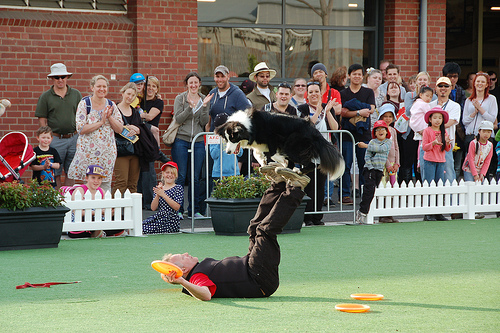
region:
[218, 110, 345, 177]
A dog on the man's feet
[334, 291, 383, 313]
Frisbees on the ground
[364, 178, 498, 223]
A small fence near the people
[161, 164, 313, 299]
The man is lifting up a dog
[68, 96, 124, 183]
The woman is wearing a dress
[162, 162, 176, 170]
The girl is wearing a hat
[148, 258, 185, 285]
A frisbee in the man's right hand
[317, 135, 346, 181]
The tail of the dog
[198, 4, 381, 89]
A window on the building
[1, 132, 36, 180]
A stroller by the plants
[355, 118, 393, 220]
A kid wearing a pink hat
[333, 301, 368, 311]
Yellow frisbee on the ground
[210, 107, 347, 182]
Dog being lifted up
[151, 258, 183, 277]
A yellow frisbee in hand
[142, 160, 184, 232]
A girl wearing a red hat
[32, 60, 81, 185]
A man wearing a green shirt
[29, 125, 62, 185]
A boy watching an entertainer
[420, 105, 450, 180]
Girl wearing a pink t shirt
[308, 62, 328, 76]
A gray hat being worn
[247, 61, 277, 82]
A hat being worn by a guy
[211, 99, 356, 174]
canine doing a trick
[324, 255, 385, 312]
frisbees on the ground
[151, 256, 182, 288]
frisbee on man's hand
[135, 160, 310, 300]
man performing stunt with dog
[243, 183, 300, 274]
pants on the man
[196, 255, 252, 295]
vest on the man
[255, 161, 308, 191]
shoes on the man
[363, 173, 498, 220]
fence on the lawn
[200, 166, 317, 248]
pot with plant in it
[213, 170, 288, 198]
plant in the pot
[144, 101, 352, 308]
A man doing frisbee tricks with a dog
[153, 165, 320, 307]
this is a man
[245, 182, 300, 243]
these are the legs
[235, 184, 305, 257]
the legs are up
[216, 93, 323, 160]
this is a dog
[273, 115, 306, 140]
the dog is black in color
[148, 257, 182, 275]
this is a frisbee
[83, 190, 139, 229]
this is a fence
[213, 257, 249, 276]
this is the belly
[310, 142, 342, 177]
this is the tail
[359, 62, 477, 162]
these are the viewers